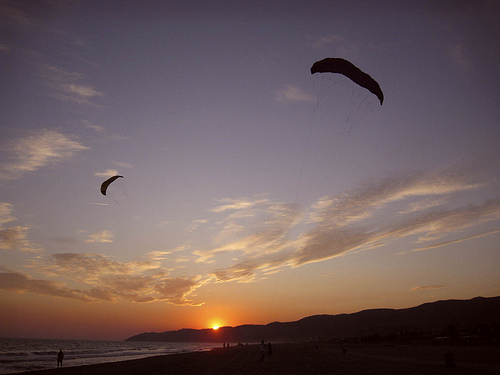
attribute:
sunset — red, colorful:
[186, 316, 235, 330]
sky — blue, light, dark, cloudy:
[0, 0, 499, 341]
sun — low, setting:
[210, 317, 224, 331]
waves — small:
[0, 349, 47, 361]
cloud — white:
[50, 252, 124, 284]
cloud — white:
[154, 279, 199, 304]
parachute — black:
[99, 173, 125, 196]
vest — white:
[260, 344, 264, 350]